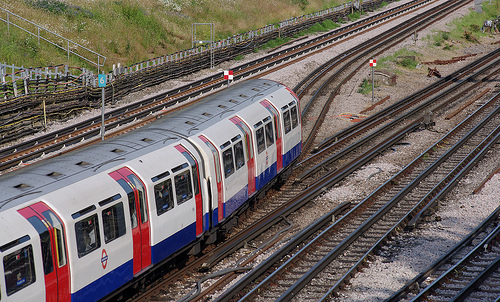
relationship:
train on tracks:
[0, 78, 301, 302] [292, 22, 497, 292]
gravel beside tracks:
[350, 134, 496, 292] [289, 147, 474, 292]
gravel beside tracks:
[178, 64, 496, 294] [289, 147, 474, 292]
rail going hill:
[1, 9, 108, 76] [2, 1, 345, 98]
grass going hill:
[60, 14, 173, 63] [26, 12, 138, 69]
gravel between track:
[174, 81, 496, 300] [241, 103, 495, 300]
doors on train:
[18, 194, 73, 299] [0, 78, 301, 302]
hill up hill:
[0, 0, 356, 77] [0, 0, 386, 97]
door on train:
[82, 164, 162, 242] [0, 78, 301, 302]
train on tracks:
[201, 89, 297, 187] [254, 208, 360, 276]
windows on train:
[70, 208, 105, 255] [0, 78, 301, 302]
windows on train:
[98, 194, 138, 242] [0, 78, 301, 302]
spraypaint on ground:
[341, 107, 359, 126] [331, 95, 353, 106]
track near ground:
[241, 48, 500, 302] [331, 95, 353, 106]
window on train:
[233, 139, 245, 170] [0, 78, 301, 302]